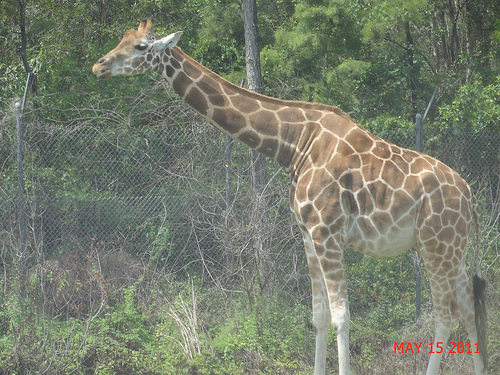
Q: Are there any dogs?
A: No, there are no dogs.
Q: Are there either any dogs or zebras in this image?
A: No, there are no dogs or zebras.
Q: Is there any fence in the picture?
A: Yes, there is a fence.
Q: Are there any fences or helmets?
A: Yes, there is a fence.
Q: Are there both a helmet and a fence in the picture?
A: No, there is a fence but no helmets.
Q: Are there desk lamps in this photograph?
A: No, there are no desk lamps.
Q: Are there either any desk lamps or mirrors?
A: No, there are no desk lamps or mirrors.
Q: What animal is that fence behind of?
A: The fence is behind the giraffe.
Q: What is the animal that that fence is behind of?
A: The animal is a giraffe.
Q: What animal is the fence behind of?
A: The fence is behind the giraffe.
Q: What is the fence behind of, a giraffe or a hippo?
A: The fence is behind a giraffe.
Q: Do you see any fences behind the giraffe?
A: Yes, there is a fence behind the giraffe.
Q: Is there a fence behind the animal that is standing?
A: Yes, there is a fence behind the giraffe.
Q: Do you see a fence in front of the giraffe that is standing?
A: No, the fence is behind the giraffe.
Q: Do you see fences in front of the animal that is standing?
A: No, the fence is behind the giraffe.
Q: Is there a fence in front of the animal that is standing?
A: No, the fence is behind the giraffe.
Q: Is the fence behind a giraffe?
A: Yes, the fence is behind a giraffe.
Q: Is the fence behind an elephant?
A: No, the fence is behind a giraffe.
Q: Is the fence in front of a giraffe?
A: No, the fence is behind a giraffe.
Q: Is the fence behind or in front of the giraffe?
A: The fence is behind the giraffe.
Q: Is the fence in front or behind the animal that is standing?
A: The fence is behind the giraffe.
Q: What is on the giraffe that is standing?
A: The fence is on the giraffe.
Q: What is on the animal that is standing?
A: The fence is on the giraffe.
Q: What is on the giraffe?
A: The fence is on the giraffe.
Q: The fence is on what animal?
A: The fence is on the giraffe.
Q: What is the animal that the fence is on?
A: The animal is a giraffe.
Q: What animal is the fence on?
A: The fence is on the giraffe.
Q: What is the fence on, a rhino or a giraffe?
A: The fence is on a giraffe.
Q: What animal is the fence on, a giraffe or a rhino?
A: The fence is on a giraffe.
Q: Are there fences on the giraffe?
A: Yes, there is a fence on the giraffe.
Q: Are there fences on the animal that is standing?
A: Yes, there is a fence on the giraffe.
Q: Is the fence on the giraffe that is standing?
A: Yes, the fence is on the giraffe.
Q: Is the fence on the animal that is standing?
A: Yes, the fence is on the giraffe.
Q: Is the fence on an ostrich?
A: No, the fence is on the giraffe.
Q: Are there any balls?
A: No, there are no balls.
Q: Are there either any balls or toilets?
A: No, there are no balls or toilets.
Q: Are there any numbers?
A: Yes, there are numbers.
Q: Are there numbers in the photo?
A: Yes, there are numbers.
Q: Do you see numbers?
A: Yes, there are numbers.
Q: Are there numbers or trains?
A: Yes, there are numbers.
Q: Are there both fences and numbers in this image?
A: Yes, there are both numbers and a fence.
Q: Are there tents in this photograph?
A: No, there are no tents.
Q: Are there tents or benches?
A: No, there are no tents or benches.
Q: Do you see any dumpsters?
A: No, there are no dumpsters.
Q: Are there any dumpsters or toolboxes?
A: No, there are no dumpsters or toolboxes.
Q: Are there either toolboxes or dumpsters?
A: No, there are no dumpsters or toolboxes.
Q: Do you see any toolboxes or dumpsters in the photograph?
A: No, there are no dumpsters or toolboxes.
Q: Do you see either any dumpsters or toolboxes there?
A: No, there are no dumpsters or toolboxes.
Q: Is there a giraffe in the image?
A: Yes, there is a giraffe.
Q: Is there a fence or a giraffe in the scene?
A: Yes, there is a giraffe.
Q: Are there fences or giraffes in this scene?
A: Yes, there is a giraffe.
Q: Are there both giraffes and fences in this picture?
A: Yes, there are both a giraffe and a fence.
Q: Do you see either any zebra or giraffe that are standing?
A: Yes, the giraffe is standing.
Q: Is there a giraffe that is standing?
A: Yes, there is a giraffe that is standing.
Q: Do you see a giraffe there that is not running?
A: Yes, there is a giraffe that is standing .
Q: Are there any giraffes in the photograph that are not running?
A: Yes, there is a giraffe that is standing.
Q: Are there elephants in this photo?
A: No, there are no elephants.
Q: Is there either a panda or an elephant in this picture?
A: No, there are no elephants or pandas.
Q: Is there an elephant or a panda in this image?
A: No, there are no elephants or pandas.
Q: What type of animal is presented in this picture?
A: The animal is a giraffe.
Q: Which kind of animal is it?
A: The animal is a giraffe.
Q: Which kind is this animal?
A: This is a giraffe.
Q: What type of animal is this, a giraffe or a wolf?
A: This is a giraffe.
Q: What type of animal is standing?
A: The animal is a giraffe.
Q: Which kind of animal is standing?
A: The animal is a giraffe.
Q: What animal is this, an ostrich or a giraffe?
A: This is a giraffe.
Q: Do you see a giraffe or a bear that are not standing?
A: No, there is a giraffe but it is standing.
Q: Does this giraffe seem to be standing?
A: Yes, the giraffe is standing.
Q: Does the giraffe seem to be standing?
A: Yes, the giraffe is standing.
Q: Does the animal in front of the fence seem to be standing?
A: Yes, the giraffe is standing.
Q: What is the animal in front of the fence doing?
A: The giraffe is standing.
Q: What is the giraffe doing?
A: The giraffe is standing.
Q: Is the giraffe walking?
A: No, the giraffe is standing.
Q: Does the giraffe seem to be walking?
A: No, the giraffe is standing.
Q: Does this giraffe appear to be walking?
A: No, the giraffe is standing.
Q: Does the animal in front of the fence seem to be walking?
A: No, the giraffe is standing.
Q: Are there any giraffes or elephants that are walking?
A: No, there is a giraffe but it is standing.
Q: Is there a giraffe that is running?
A: No, there is a giraffe but it is standing.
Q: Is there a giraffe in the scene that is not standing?
A: No, there is a giraffe but it is standing.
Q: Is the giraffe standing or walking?
A: The giraffe is standing.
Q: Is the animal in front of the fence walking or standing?
A: The giraffe is standing.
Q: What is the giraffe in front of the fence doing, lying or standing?
A: The giraffe is standing.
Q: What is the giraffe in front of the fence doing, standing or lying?
A: The giraffe is standing.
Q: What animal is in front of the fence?
A: The giraffe is in front of the fence.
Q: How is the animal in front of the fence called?
A: The animal is a giraffe.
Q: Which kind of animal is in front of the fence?
A: The animal is a giraffe.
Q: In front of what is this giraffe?
A: The giraffe is in front of the fence.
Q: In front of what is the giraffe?
A: The giraffe is in front of the fence.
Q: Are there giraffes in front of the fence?
A: Yes, there is a giraffe in front of the fence.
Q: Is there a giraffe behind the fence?
A: No, the giraffe is in front of the fence.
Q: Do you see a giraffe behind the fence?
A: No, the giraffe is in front of the fence.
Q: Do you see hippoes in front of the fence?
A: No, there is a giraffe in front of the fence.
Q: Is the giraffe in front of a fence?
A: Yes, the giraffe is in front of a fence.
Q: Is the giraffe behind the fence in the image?
A: No, the giraffe is in front of the fence.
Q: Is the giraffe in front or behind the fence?
A: The giraffe is in front of the fence.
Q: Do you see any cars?
A: No, there are no cars.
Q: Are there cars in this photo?
A: No, there are no cars.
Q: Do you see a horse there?
A: No, there are no horses.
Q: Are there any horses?
A: No, there are no horses.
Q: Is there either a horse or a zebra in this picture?
A: No, there are no horses or zebras.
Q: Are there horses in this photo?
A: No, there are no horses.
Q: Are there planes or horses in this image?
A: No, there are no horses or planes.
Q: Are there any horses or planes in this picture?
A: No, there are no horses or planes.